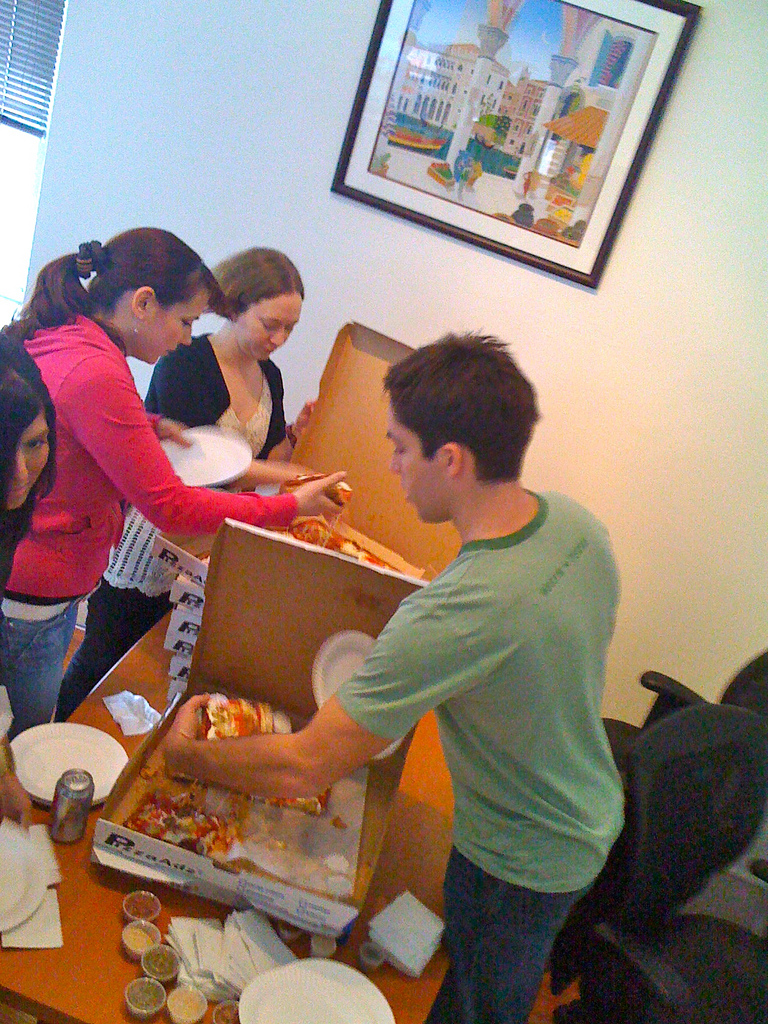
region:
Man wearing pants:
[416, 812, 620, 1017]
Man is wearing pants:
[437, 810, 620, 1021]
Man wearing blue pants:
[430, 803, 605, 1022]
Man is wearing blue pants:
[437, 816, 605, 1022]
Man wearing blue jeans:
[426, 805, 623, 1022]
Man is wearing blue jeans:
[431, 809, 620, 1018]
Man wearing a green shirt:
[326, 486, 644, 901]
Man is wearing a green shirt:
[332, 484, 639, 905]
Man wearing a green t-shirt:
[324, 486, 638, 904]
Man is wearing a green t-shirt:
[336, 488, 632, 904]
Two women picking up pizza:
[41, 204, 431, 623]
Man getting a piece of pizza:
[165, 314, 627, 1020]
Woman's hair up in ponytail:
[25, 208, 223, 398]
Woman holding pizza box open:
[199, 197, 332, 478]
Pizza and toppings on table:
[72, 660, 417, 1017]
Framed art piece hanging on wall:
[335, 7, 691, 303]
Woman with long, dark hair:
[0, 347, 81, 615]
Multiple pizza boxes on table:
[93, 314, 526, 960]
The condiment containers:
[93, 884, 218, 1014]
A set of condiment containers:
[107, 881, 223, 1020]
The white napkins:
[164, 903, 291, 998]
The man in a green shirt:
[293, 505, 657, 1004]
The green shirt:
[335, 504, 660, 894]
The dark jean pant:
[436, 834, 565, 1018]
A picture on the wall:
[331, 3, 677, 298]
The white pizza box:
[76, 552, 450, 944]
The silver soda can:
[37, 759, 107, 852]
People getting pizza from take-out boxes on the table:
[0, 223, 631, 1023]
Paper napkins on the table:
[365, 884, 445, 978]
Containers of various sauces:
[116, 878, 248, 1021]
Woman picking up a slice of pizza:
[0, 223, 358, 726]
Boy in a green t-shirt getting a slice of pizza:
[158, 335, 628, 1016]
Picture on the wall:
[329, 3, 706, 292]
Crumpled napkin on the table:
[100, 675, 164, 740]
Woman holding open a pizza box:
[145, 240, 466, 574]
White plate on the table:
[8, 713, 131, 813]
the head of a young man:
[376, 332, 592, 540]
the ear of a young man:
[436, 431, 477, 484]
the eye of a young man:
[386, 431, 440, 457]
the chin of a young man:
[401, 486, 475, 538]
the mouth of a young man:
[388, 462, 451, 538]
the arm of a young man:
[162, 580, 504, 832]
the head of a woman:
[215, 245, 351, 389]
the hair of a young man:
[384, 339, 566, 496]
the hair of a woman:
[26, 141, 306, 356]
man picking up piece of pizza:
[133, 316, 625, 1014]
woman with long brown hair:
[1, 328, 78, 590]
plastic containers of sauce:
[115, 887, 208, 1017]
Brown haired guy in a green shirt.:
[161, 322, 625, 1020]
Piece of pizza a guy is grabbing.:
[200, 694, 275, 736]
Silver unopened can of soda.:
[45, 769, 94, 843]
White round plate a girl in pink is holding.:
[160, 419, 251, 487]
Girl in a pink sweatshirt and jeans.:
[0, 221, 347, 737]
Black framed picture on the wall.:
[327, 1, 701, 291]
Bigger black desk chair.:
[553, 702, 764, 1022]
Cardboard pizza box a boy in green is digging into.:
[90, 517, 431, 939]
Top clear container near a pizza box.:
[121, 887, 161, 925]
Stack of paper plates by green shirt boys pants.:
[237, 956, 397, 1021]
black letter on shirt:
[538, 584, 551, 597]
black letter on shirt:
[546, 569, 562, 584]